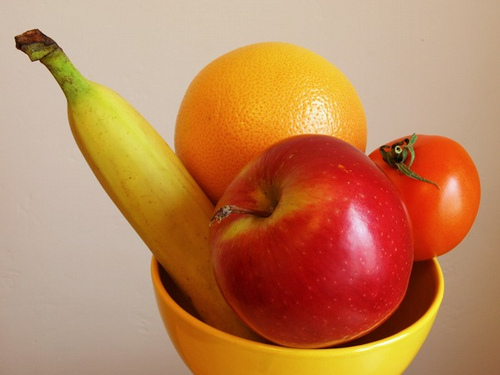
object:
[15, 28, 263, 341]
banana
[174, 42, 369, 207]
fruit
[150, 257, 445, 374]
bowl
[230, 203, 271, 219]
stem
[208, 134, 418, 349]
apple